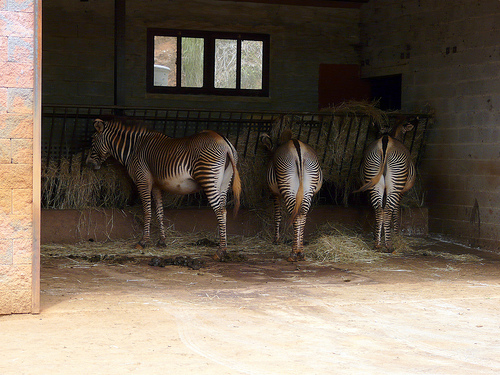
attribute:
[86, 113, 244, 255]
zebra — eating, turned, inside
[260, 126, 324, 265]
zebra — eating, three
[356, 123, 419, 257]
zebra — eating, turned-around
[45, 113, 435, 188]
feeder — metal, rusted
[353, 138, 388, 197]
tail — swinging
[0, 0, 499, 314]
wall — brick, cement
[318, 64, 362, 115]
door — red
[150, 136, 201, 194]
body — stripped